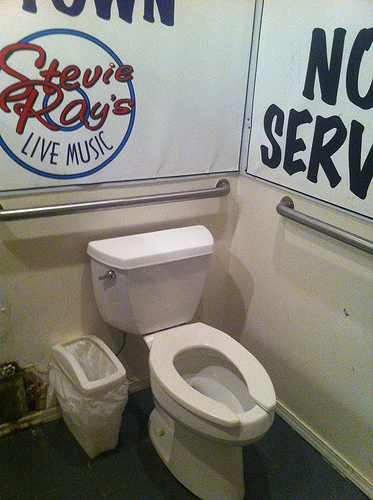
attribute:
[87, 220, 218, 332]
tank — white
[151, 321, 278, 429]
toilet seat — white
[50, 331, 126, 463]
trash can — white, small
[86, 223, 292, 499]
toilet — white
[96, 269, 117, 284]
lever — metal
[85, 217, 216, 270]
tank lid — white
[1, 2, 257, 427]
wall — ripped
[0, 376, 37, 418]
wall stain — dark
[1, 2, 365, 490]
bathroom — old, dirty, nasty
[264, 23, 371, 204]
letters — black